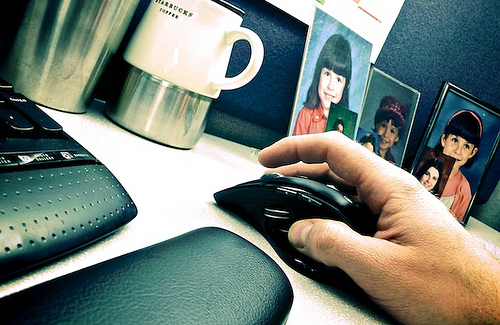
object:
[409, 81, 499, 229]
picture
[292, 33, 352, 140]
girl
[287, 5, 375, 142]
picture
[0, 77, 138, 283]
keyboard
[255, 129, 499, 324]
person´s hand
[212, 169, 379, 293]
mouse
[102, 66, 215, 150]
cup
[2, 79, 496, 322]
desk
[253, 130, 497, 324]
person